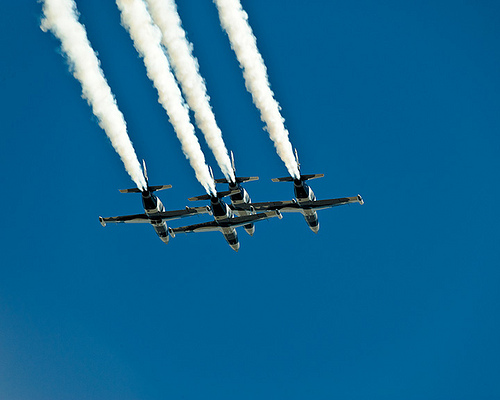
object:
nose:
[156, 232, 171, 245]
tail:
[67, 17, 358, 155]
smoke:
[37, 0, 304, 175]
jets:
[92, 173, 367, 253]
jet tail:
[210, 173, 260, 185]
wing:
[165, 204, 211, 219]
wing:
[240, 197, 296, 210]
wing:
[166, 218, 232, 238]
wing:
[313, 194, 363, 214]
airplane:
[160, 172, 285, 251]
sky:
[300, 6, 492, 124]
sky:
[31, 244, 458, 377]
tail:
[118, 160, 171, 192]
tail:
[269, 149, 326, 181]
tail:
[187, 181, 239, 200]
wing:
[231, 205, 287, 232]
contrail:
[208, 0, 302, 179]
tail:
[210, 169, 261, 189]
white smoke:
[214, 1, 308, 180]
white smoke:
[113, 0, 250, 195]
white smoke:
[38, 1, 158, 193]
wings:
[95, 202, 150, 230]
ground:
[377, 40, 440, 112]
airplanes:
[95, 171, 203, 247]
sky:
[352, 103, 485, 340]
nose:
[234, 245, 242, 255]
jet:
[166, 198, 286, 253]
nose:
[307, 216, 321, 234]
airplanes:
[268, 149, 363, 238]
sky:
[1, 4, 496, 397]